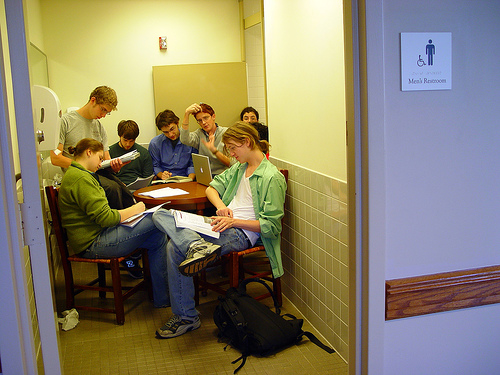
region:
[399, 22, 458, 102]
Sign on wall for Men's Restroom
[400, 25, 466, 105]
Restroom sign is white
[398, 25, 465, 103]
Restroom will acommodate handicaped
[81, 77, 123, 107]
Boy has light hair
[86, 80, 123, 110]
Boys hair is light brown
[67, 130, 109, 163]
Girl has dark hair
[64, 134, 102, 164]
Girls hair is brown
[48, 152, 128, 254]
Girl wearing a green shirt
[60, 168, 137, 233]
Green shirt has long sleeve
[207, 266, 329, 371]
Black book bag laying on floor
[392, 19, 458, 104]
a small warning on wall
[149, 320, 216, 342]
shoe of a guy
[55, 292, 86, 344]
small dust thrown on floor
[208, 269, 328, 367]
a small bag of the person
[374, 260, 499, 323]
a small portion of wooden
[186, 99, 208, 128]
a hand of a white guy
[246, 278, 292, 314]
one strip of the bag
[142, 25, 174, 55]
a small object on the wall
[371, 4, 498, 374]
a white beautiful door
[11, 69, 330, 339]
group of person sitting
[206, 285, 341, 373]
Black bookbag on floor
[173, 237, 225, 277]
Man wears grey sneakers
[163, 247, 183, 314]
Man wears blue jeans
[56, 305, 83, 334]
White tissue on floor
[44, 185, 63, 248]
Back of brown chair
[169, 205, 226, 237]
Open book on man's lap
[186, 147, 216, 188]
Grey laptop on table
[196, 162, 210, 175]
Apple sign on laptop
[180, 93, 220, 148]
Woman's hand on head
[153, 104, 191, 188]
Man looking down at paper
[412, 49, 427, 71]
A handicap symbol on a sign.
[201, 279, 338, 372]
A black backpack on the floor.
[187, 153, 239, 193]
A silver Apple laptop.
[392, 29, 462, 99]
A men's bathroom sign hanging on the wall.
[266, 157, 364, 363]
Beige tiles on the wall.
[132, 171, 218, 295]
A round wooden table.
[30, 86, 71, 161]
A white paper towel dispenser.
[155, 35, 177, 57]
A fire alarm indicator.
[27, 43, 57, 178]
A mirror on the wall.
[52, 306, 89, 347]
A paper towel on the ground.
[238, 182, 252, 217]
Man wear white under shirt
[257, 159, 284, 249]
Man wears green long sleeve shirt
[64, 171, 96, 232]
Woman wears green sweater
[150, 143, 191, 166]
Man wears blue shirt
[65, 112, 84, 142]
Man wears grey tshirt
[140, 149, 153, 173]
Man wears green long sleeve shirt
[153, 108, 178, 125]
Man's hair is dark brown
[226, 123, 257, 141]
Man's hair is dirty blonde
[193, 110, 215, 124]
Man wears glasses on face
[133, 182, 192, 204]
White book open on table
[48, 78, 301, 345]
A group of students studying in a bathroom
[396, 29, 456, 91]
A sign on the door of a men's restroom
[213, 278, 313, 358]
A brown backpack on a floor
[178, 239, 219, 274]
A white and gray tennis shoe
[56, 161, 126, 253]
A green sweater on a woman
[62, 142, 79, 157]
A bun on the head of a woman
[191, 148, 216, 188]
A silver laptop on a computer